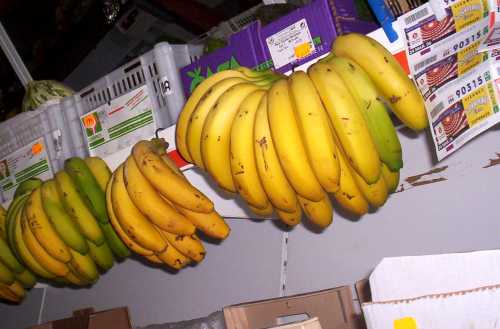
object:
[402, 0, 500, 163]
paper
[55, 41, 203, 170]
crate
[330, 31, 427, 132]
bananas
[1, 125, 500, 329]
wall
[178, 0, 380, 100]
cardboard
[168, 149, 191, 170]
stripe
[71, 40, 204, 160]
bin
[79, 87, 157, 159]
label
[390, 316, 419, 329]
sticker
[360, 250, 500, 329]
box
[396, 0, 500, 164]
coupon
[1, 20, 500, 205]
shelf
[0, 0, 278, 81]
ceiling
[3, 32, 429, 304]
bunch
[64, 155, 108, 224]
banana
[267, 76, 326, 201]
banana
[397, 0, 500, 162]
paper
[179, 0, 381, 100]
box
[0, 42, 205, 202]
containers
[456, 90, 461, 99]
number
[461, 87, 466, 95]
number 0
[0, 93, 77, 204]
crate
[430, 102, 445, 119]
bar code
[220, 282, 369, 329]
box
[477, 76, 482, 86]
numbers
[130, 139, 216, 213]
banana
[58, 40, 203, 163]
crate